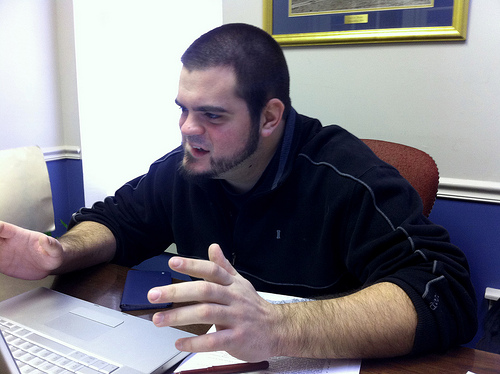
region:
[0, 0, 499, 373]
the interior of an office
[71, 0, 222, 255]
a window in the office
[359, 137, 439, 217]
a brown office chair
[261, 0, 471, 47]
a picture on the wall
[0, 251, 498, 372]
a wooden office desk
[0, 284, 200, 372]
a silver laptop computer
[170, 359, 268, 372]
a pen on the desk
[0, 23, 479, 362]
a man sitting at the desk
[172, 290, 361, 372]
a paper on the desk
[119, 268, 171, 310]
a blue book on the desk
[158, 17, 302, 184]
buzzed head of man at table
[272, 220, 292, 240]
zipper on front of shirt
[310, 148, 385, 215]
white line going down shoulder of man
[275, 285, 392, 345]
hair forearm of man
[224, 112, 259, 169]
trimmed beard of face of man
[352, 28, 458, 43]
golden frame of picture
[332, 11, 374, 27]
golden plaque on picture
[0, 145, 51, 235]
white chair of room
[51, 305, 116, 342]
white trackpad in room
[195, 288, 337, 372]
white paper on top of table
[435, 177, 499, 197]
CHAIR RAIL IS AROUND ROOM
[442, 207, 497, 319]
LOWER PORTION OF WALL IS BLUE IN COLOR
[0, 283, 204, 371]
LAP TOP IS IN FRONT OF MAN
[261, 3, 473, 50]
PICTURE FRAME ON BACK WALL IS GOLD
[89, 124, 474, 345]
MAN IS WEARING A BLUE SHIRT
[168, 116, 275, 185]
MAN HAS A FULL BEARD ON HIS FACE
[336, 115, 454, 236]
CHAIR IS RED IN COLOR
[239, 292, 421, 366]
MAN HAS LOTS OF HAIR ON HIS ARM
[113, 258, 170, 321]
A LITTLE BLACK BOOK IS ON THE TABLE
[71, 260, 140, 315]
TABLE IS BROWN IN COLOR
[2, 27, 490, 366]
person wearing a dark blue clothing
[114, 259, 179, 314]
a checkbook on top of table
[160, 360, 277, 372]
a red pen on top of table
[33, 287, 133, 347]
mouse tracking pad of laptop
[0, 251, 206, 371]
keyboard of a laptop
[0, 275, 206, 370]
a laptop on top of table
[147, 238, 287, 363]
hands of a person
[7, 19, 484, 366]
person sitting on a chair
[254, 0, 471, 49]
paintings on a wall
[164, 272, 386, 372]
papers on a table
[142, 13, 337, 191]
man with shaved haircut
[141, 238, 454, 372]
hairy arms of man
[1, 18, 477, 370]
man sitting at office desk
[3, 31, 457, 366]
man sitting at lap top computer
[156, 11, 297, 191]
man with shaved head and beard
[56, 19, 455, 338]
brunette man in dark sweater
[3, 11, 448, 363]
man staring at laptop screen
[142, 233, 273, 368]
man's clean white hand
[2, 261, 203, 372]
silver laptop on desk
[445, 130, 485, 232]
white and blue painted wall